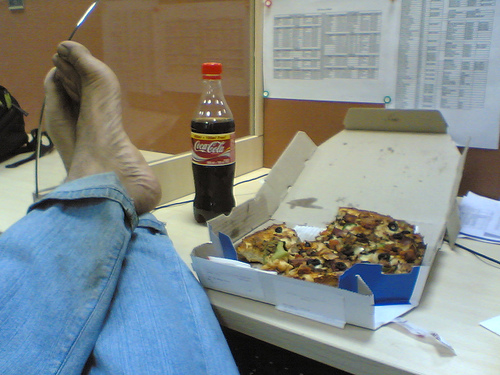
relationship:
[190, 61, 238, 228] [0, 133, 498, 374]
soda bottle on desk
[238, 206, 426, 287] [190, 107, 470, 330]
pizza in box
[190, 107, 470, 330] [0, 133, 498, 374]
box on desk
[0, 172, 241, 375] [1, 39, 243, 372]
jeans on legs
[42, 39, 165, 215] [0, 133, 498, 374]
feet on desk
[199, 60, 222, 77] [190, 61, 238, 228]
lid on soda bottle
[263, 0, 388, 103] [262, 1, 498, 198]
paper on wall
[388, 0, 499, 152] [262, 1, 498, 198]
paper on wall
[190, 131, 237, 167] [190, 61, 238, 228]
label on soda bottle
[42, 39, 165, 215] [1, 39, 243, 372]
feet on legs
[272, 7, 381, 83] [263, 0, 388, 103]
print on paper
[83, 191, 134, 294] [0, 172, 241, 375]
dirt on jeans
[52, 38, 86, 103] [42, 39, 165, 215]
toes on feet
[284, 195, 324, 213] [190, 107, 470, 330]
stain on box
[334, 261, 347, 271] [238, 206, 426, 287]
olive on pizza